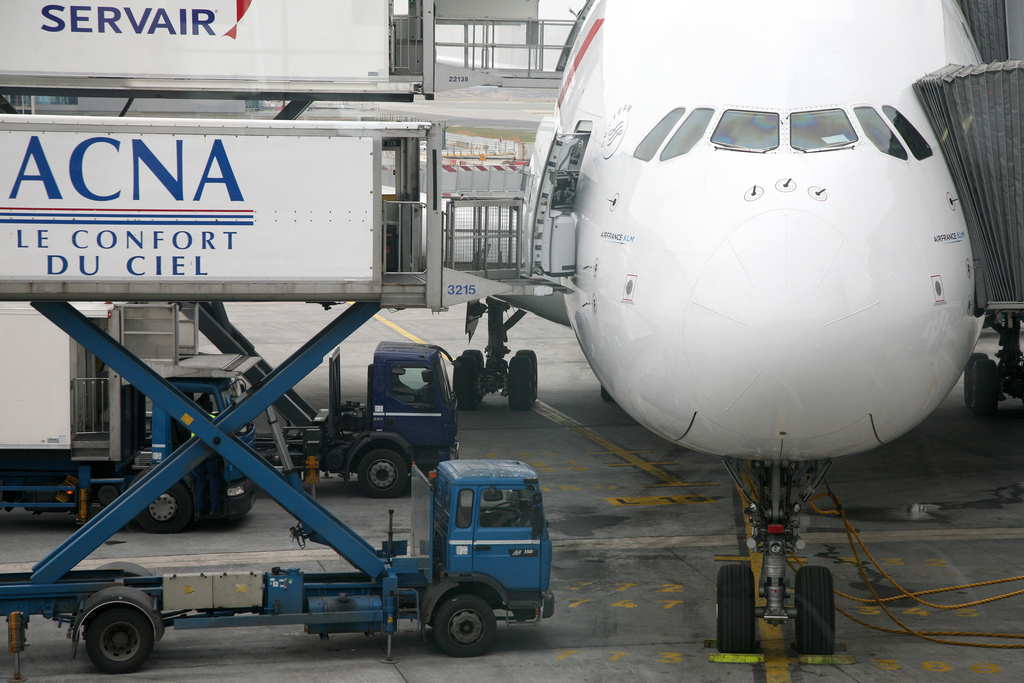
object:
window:
[632, 107, 715, 161]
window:
[710, 108, 780, 153]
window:
[391, 363, 438, 411]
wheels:
[715, 555, 836, 656]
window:
[476, 483, 533, 531]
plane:
[452, 0, 982, 683]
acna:
[8, 136, 246, 201]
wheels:
[69, 585, 164, 674]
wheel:
[789, 565, 833, 657]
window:
[852, 104, 931, 161]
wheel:
[714, 565, 758, 656]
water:
[547, 503, 695, 579]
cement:
[0, 301, 1024, 683]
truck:
[0, 460, 555, 672]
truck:
[0, 302, 461, 535]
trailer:
[0, 113, 444, 298]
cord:
[810, 487, 1023, 653]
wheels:
[452, 350, 538, 411]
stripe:
[548, 2, 605, 109]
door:
[469, 487, 542, 591]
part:
[221, 0, 252, 40]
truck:
[0, 0, 433, 119]